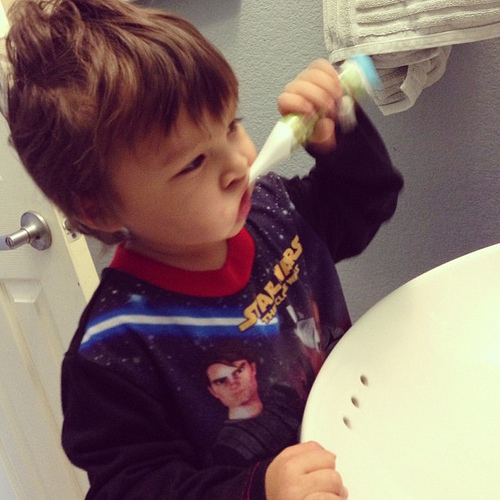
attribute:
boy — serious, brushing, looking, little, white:
[15, 11, 334, 288]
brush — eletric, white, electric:
[266, 54, 385, 163]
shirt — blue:
[113, 251, 316, 435]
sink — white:
[358, 251, 497, 494]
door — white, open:
[10, 269, 60, 372]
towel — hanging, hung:
[328, 5, 464, 63]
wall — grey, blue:
[263, 10, 305, 50]